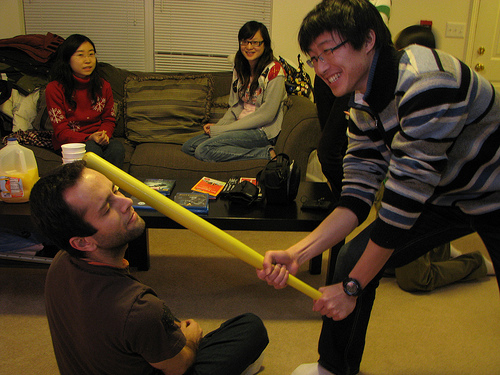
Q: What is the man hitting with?
A: Bat.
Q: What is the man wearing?
A: Glasses.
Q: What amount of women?
A: Two.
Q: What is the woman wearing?
A: Sweater.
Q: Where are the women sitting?
A: Couch.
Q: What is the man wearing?
A: Glasses.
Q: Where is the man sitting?
A: Floor.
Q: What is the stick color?
A: Yellow.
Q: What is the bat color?
A: Yellow.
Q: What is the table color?
A: Black.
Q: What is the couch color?
A: Black.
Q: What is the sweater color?
A: Red.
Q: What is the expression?
A: Smile.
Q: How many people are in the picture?
A: Five.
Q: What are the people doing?
A: Playing.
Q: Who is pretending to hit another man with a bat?
A: The man in glasses.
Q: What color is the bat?
A: Yellow.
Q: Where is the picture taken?
A: Living room.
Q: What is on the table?
A: Orange juice.